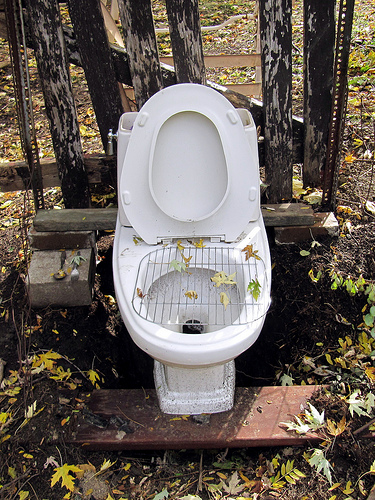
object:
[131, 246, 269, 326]
grill grate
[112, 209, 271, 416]
toilet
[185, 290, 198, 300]
leaves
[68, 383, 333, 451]
wood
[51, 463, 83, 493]
leaf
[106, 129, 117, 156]
handle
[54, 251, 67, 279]
silverware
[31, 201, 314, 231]
wood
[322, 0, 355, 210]
rod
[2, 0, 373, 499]
ground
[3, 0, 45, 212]
rod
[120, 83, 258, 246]
seat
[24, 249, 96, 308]
block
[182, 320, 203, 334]
hole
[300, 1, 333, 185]
woods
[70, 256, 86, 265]
leaf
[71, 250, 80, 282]
fork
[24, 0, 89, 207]
trunks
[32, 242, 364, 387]
dirt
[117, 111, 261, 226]
tank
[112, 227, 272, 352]
bowl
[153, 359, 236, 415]
base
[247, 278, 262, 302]
leaves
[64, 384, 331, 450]
board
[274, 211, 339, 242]
brick